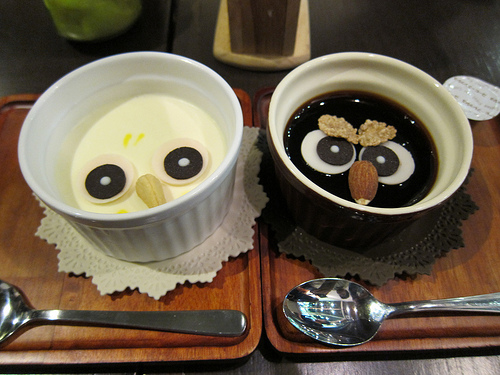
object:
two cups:
[15, 51, 475, 264]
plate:
[252, 86, 498, 355]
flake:
[317, 114, 396, 148]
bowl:
[266, 52, 474, 216]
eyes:
[300, 129, 416, 185]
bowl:
[17, 50, 244, 263]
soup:
[312, 97, 417, 177]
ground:
[199, 0, 323, 73]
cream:
[52, 94, 226, 215]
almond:
[348, 160, 378, 205]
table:
[0, 0, 492, 375]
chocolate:
[282, 90, 438, 208]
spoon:
[0, 278, 247, 346]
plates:
[0, 88, 260, 364]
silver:
[281, 277, 500, 348]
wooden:
[319, 245, 494, 301]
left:
[0, 45, 59, 373]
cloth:
[256, 127, 481, 287]